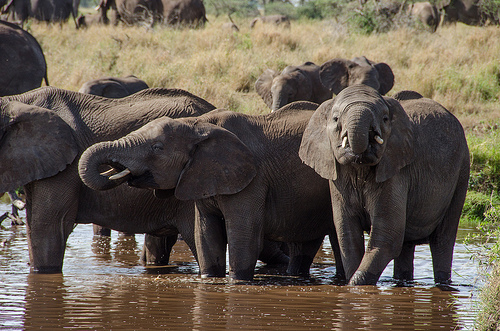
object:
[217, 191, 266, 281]
leg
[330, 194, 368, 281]
leg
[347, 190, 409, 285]
leg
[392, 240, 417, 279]
leg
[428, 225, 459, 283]
leg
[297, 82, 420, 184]
head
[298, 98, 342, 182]
ear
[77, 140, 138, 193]
trunk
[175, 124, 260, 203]
ear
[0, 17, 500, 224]
riverbank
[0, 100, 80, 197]
ear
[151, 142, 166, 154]
eye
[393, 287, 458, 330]
reflection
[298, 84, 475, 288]
elephant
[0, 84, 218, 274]
elephant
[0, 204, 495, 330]
lake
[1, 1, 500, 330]
park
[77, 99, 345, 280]
elephant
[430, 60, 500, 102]
grass